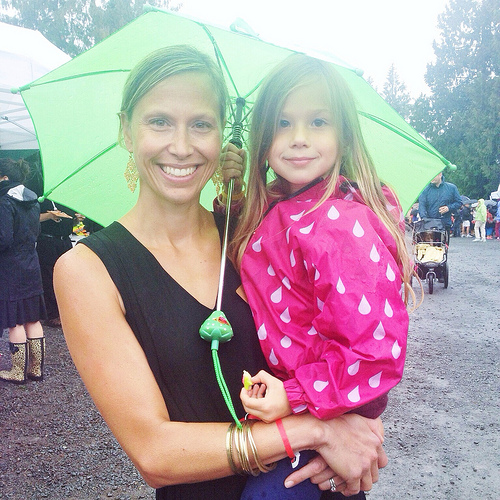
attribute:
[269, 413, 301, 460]
band — red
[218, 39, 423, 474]
girl — little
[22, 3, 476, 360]
umbrella — buttom part 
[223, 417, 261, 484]
bangles — group 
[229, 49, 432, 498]
girl — cute, little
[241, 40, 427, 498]
girl — young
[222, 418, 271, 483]
bracelets — gold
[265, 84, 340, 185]
girl's face — face , cute 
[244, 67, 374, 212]
hair — long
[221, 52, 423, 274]
hair — blond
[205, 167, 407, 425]
coat — pink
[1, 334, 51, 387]
boots — rubber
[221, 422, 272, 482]
bracelets — gold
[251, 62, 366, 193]
girl — face 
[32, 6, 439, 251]
umbrella — green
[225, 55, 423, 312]
hair — blonde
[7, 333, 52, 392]
boots — leopard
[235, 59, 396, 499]
girl — young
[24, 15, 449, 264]
umbrella — green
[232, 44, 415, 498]
girl — young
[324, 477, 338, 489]
wedding rings — silver